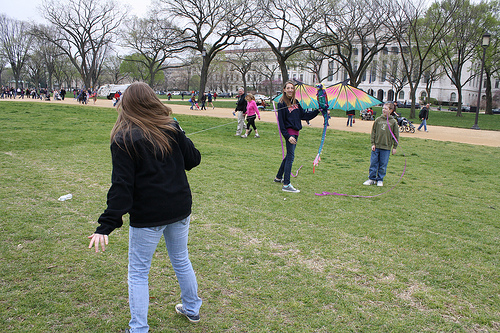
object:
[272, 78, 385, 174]
kite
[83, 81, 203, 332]
girl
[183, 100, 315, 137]
kite string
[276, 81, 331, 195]
girl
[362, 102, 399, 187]
boy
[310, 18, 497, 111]
building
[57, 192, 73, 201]
bottle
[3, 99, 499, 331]
grass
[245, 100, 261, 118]
jacket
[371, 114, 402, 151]
sweatshirt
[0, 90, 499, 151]
walking path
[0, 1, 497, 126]
background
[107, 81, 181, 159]
hair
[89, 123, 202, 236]
jacket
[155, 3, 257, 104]
tree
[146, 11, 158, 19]
leaves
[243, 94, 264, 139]
people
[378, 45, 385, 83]
columns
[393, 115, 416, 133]
stroller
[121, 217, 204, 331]
jeans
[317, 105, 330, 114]
girl's hadn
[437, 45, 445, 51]
leaves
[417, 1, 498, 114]
tree